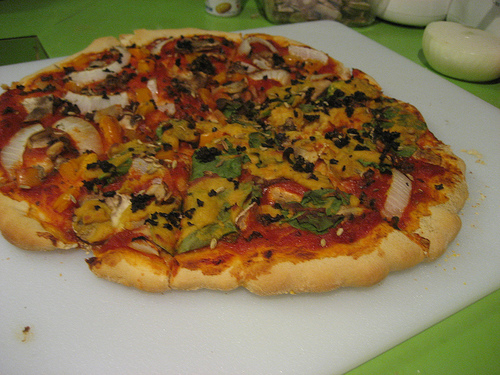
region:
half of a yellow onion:
[420, 20, 498, 81]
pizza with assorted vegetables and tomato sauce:
[0, 26, 468, 296]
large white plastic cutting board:
[2, 18, 497, 373]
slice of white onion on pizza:
[51, 114, 102, 152]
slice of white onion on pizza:
[382, 167, 412, 222]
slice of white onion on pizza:
[2, 123, 42, 170]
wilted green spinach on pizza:
[286, 187, 355, 233]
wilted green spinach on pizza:
[189, 150, 250, 179]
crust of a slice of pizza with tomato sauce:
[170, 226, 423, 296]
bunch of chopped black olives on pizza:
[194, 145, 224, 164]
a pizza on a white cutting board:
[6, 19, 471, 298]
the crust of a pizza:
[260, 264, 352, 294]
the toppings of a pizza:
[144, 94, 273, 204]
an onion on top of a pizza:
[59, 114, 104, 161]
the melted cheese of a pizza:
[194, 184, 214, 214]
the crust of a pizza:
[137, 21, 224, 42]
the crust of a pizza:
[424, 171, 469, 259]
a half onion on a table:
[421, 20, 498, 85]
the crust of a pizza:
[2, 197, 68, 258]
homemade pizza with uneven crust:
[4, 25, 469, 296]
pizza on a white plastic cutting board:
[1, 19, 495, 374]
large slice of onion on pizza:
[377, 165, 413, 222]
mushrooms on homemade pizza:
[28, 131, 70, 161]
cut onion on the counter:
[418, 17, 498, 84]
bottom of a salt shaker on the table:
[204, 0, 244, 17]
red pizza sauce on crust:
[245, 231, 376, 250]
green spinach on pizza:
[187, 148, 249, 179]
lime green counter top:
[4, 3, 495, 370]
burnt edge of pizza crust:
[82, 253, 102, 270]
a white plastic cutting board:
[6, 20, 498, 373]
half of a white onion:
[420, 23, 498, 80]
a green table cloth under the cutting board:
[5, 2, 493, 369]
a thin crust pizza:
[6, 29, 465, 284]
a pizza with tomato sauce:
[12, 26, 469, 290]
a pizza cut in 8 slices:
[5, 27, 467, 289]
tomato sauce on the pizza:
[6, 46, 437, 236]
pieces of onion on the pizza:
[5, 38, 410, 218]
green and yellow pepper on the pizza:
[68, 80, 417, 238]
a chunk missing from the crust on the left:
[49, 235, 104, 267]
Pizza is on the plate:
[1, 15, 486, 302]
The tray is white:
[8, 297, 255, 370]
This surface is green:
[393, 325, 499, 371]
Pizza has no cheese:
[3, 23, 470, 307]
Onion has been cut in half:
[411, 6, 498, 93]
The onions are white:
[410, 14, 497, 101]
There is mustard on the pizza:
[84, 99, 341, 302]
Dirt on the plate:
[7, 298, 131, 352]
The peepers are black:
[163, 117, 252, 182]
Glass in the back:
[193, 3, 378, 45]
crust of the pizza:
[300, 260, 381, 293]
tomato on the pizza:
[147, 112, 181, 123]